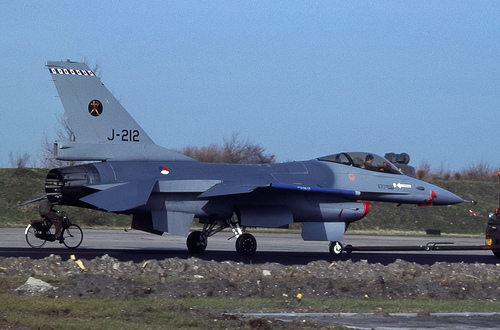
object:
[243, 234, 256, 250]
rim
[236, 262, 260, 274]
ground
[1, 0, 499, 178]
sky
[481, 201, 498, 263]
car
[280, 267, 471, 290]
dirt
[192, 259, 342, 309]
water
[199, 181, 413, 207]
jets wing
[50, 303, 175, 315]
grass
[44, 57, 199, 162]
tail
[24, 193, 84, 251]
person/bicycle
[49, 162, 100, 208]
engine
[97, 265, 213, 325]
ground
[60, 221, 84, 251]
front tire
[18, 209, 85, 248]
bicycle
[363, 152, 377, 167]
pilot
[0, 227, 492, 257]
road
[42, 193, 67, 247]
person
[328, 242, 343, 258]
wheel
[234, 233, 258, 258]
wheel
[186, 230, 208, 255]
wheel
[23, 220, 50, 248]
wheel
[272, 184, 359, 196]
edge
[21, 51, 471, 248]
jet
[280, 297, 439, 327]
ground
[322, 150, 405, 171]
cockpit